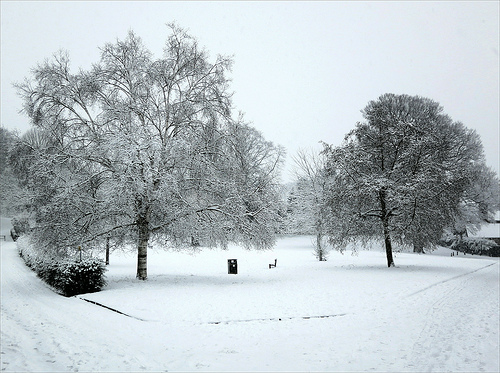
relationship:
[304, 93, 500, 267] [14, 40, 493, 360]
tree covered with snow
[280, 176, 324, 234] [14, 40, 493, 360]
tree covered with snow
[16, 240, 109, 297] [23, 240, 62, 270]
bush with snow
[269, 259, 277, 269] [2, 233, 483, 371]
bench in snow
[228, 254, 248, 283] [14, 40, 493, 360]
can standing in snow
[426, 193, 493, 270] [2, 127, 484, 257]
house standing in background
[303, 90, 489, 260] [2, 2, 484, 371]
tree shown in photo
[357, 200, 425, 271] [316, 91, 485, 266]
branch growing on tree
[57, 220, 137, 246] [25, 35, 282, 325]
branch growing on tree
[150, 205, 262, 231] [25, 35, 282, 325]
branch growing on tree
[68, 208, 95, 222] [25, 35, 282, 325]
branch growing on tree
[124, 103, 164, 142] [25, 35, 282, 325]
branch growing on tree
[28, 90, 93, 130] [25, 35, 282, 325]
branch growing on tree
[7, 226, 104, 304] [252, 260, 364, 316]
bush growing in ground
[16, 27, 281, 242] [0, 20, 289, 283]
snow covering tree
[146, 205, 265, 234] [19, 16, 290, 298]
branch growing on tree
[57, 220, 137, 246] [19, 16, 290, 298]
branch growing on tree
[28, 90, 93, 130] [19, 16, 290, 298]
branch growing on tree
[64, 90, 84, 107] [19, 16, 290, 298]
branch growing on tree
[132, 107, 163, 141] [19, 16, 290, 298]
branch growing on tree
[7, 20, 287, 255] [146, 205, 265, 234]
snow covering branch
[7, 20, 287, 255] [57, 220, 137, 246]
snow covering branch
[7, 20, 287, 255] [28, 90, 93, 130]
snow covering branch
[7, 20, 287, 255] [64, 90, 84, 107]
snow covering branch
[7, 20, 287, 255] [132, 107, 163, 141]
snow covering branch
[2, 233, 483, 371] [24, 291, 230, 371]
snow covering ground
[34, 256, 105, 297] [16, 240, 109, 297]
snow covering bush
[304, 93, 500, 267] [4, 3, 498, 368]
tree in winter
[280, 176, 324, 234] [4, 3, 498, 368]
tree in winter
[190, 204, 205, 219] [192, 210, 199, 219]
branch seen part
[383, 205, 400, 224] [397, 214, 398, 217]
branch has part